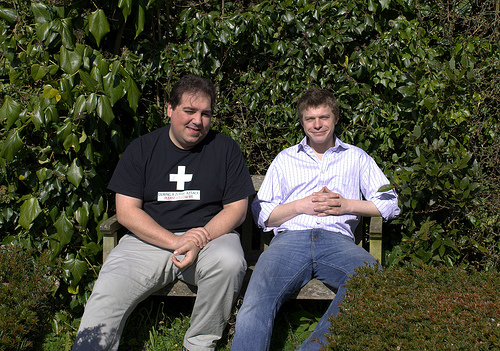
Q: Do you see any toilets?
A: No, there are no toilets.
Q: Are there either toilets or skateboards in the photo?
A: No, there are no toilets or skateboards.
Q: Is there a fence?
A: No, there are no fences.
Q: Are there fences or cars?
A: No, there are no fences or cars.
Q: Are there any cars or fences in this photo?
A: No, there are no fences or cars.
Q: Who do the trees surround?
A: The trees surround the men.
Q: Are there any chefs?
A: No, there are no chefs.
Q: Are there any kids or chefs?
A: No, there are no chefs or kids.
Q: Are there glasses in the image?
A: No, there are no glasses.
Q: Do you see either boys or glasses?
A: No, there are no glasses or boys.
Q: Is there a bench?
A: Yes, there is a bench.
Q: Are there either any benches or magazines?
A: Yes, there is a bench.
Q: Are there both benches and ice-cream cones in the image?
A: No, there is a bench but no ice-cream cones.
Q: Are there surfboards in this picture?
A: No, there are no surfboards.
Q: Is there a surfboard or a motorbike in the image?
A: No, there are no surfboards or motorcycles.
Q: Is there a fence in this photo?
A: No, there are no fences.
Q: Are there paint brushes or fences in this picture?
A: No, there are no fences or paint brushes.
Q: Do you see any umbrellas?
A: No, there are no umbrellas.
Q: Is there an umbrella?
A: No, there are no umbrellas.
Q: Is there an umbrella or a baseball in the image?
A: No, there are no umbrellas or baseballs.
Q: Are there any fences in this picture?
A: No, there are no fences.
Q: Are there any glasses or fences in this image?
A: No, there are no fences or glasses.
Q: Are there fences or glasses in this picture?
A: No, there are no fences or glasses.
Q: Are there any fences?
A: No, there are no fences.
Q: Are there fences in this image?
A: No, there are no fences.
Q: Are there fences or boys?
A: No, there are no fences or boys.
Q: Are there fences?
A: No, there are no fences.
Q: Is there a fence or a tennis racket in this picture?
A: No, there are no fences or rackets.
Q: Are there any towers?
A: No, there are no towers.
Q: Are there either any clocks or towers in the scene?
A: No, there are no towers or clocks.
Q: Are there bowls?
A: No, there are no bowls.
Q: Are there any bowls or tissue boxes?
A: No, there are no bowls or tissue boxes.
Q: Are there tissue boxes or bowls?
A: No, there are no bowls or tissue boxes.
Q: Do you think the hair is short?
A: Yes, the hair is short.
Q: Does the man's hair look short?
A: Yes, the hair is short.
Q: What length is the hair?
A: The hair is short.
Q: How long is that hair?
A: The hair is short.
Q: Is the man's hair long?
A: No, the hair is short.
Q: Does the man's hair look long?
A: No, the hair is short.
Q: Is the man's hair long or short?
A: The hair is short.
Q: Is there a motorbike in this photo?
A: No, there are no motorcycles.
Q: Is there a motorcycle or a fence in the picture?
A: No, there are no motorcycles or fences.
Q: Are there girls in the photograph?
A: No, there are no girls.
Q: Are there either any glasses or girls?
A: No, there are no girls or glasses.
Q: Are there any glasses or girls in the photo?
A: No, there are no girls or glasses.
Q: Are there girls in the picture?
A: No, there are no girls.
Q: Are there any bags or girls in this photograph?
A: No, there are no girls or bags.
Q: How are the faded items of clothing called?
A: The clothing items are jeans.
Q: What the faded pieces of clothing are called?
A: The clothing items are jeans.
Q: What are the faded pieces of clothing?
A: The clothing items are jeans.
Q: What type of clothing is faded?
A: The clothing is jeans.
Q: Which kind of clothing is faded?
A: The clothing is jeans.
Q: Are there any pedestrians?
A: No, there are no pedestrians.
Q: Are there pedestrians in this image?
A: No, there are no pedestrians.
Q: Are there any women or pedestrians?
A: No, there are no pedestrians or women.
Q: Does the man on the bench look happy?
A: Yes, the man is happy.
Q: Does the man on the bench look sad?
A: No, the man is happy.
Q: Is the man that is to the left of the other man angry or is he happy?
A: The man is happy.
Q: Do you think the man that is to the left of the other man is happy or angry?
A: The man is happy.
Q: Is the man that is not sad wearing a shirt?
A: Yes, the man is wearing a shirt.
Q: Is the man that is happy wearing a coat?
A: No, the man is wearing a shirt.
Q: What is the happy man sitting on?
A: The man is sitting on the bench.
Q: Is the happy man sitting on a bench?
A: Yes, the man is sitting on a bench.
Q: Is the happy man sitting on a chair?
A: No, the man is sitting on a bench.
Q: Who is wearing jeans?
A: The man is wearing jeans.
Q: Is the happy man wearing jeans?
A: Yes, the man is wearing jeans.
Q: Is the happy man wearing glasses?
A: No, the man is wearing jeans.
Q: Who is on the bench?
A: The man is on the bench.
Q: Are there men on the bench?
A: Yes, there is a man on the bench.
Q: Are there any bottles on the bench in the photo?
A: No, there is a man on the bench.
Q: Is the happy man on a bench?
A: Yes, the man is on a bench.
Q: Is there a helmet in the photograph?
A: No, there are no helmets.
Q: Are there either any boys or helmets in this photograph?
A: No, there are no helmets or boys.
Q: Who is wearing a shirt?
A: The man is wearing a shirt.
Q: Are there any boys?
A: No, there are no boys.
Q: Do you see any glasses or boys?
A: No, there are no boys or glasses.